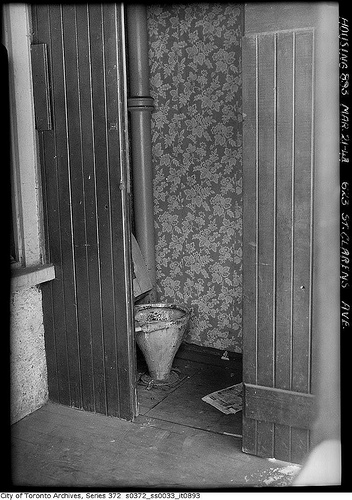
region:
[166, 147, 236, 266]
floral pattern on the wall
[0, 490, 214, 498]
black serial identification of the photo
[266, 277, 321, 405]
wood paneled surface of the doorway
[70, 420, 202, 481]
wooden surface on the floor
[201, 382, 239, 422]
discarded newspaper on the ground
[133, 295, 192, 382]
a dirty funnel shaped toilet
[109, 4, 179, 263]
metal plumbing pipe in the bathroom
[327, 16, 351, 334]
white address identification of the photo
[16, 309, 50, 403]
white stone surface of the wall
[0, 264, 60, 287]
white wooden surface of the window sill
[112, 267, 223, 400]
This is a toilet.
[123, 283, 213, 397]
The toilet is dirty.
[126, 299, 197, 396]
The toilet is made of metal.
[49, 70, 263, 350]
This is a bathroom.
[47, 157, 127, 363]
This is made of wood.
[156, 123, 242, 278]
This is the bathroom's wallpaper.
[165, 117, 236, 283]
The wallpaper is floral.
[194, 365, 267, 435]
This is a newspaper.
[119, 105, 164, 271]
This is a pipe.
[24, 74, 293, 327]
This photo is monochromatic style.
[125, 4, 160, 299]
pole running along the wall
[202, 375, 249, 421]
paper laying on the ground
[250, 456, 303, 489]
white on the ground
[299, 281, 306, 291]
small hole in the wood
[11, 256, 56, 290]
ledge on the wall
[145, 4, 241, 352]
wallpaper on the wall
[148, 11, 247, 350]
flower design on the wallpaper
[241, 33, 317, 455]
four wooden planks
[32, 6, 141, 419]
wooden planks sticking together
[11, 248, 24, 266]
corner of a window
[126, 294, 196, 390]
An old, disgusting toilet in a bathroom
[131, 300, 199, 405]
A conical toilet made of ceramic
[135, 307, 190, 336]
Dirt and feces inside of the toilet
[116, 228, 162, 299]
The back of the toilet is severely broken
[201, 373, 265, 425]
A page of newspaper lies on the ground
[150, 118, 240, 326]
A floral design on the wall of the bathroom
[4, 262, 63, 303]
A ledge of the window by the door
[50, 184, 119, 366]
A wooden door to the bathroom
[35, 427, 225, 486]
Wooden planks on the floor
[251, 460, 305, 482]
A few flecks of white paint on the wooden floor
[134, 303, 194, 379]
literal hole in the ground where people used the restroom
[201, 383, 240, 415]
aged newspaper from simpler times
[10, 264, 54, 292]
block window sill that is used for placing things on it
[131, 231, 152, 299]
homemade lid for covering the 'hole in the ground'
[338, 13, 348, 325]
writing that says this was the toronto government housing in 48'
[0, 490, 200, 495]
archives label and label number for storing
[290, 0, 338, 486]
blurry object that looks like a finger or thumb covering the lens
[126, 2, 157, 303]
plumbing pipe used for water flowage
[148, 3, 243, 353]
ivy and vine wall paper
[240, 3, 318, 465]
wood paneling used for a door